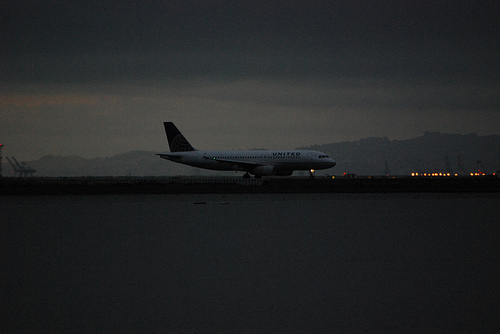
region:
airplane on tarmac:
[152, 115, 341, 192]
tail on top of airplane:
[157, 115, 202, 152]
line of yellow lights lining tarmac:
[404, 166, 498, 181]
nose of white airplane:
[318, 150, 346, 174]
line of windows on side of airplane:
[206, 153, 273, 162]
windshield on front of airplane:
[313, 150, 336, 160]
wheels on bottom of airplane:
[235, 169, 265, 182]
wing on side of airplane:
[197, 150, 267, 174]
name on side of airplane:
[267, 149, 307, 159]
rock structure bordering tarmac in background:
[5, 125, 497, 175]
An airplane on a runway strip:
[152, 113, 354, 189]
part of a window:
[311, 148, 328, 161]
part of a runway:
[350, 192, 374, 284]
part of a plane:
[199, 153, 229, 165]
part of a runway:
[244, 224, 279, 277]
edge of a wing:
[211, 147, 243, 177]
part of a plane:
[159, 135, 261, 276]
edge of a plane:
[283, 155, 298, 166]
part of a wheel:
[314, 177, 319, 184]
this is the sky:
[113, 103, 129, 117]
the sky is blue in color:
[97, 107, 140, 129]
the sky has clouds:
[217, 19, 265, 42]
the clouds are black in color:
[151, 24, 206, 57]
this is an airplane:
[137, 103, 337, 182]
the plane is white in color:
[192, 146, 207, 171]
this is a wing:
[205, 154, 260, 173]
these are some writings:
[267, 149, 304, 159]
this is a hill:
[102, 150, 133, 170]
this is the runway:
[190, 227, 262, 260]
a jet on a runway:
[135, 116, 347, 186]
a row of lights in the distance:
[370, 157, 497, 193]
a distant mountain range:
[25, 134, 497, 188]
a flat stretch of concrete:
[21, 195, 498, 331]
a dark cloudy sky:
[7, 9, 488, 147]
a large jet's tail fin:
[155, 114, 205, 154]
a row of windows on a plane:
[195, 147, 313, 169]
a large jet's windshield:
[306, 144, 334, 171]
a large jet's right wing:
[200, 144, 270, 179]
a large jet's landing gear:
[227, 165, 319, 182]